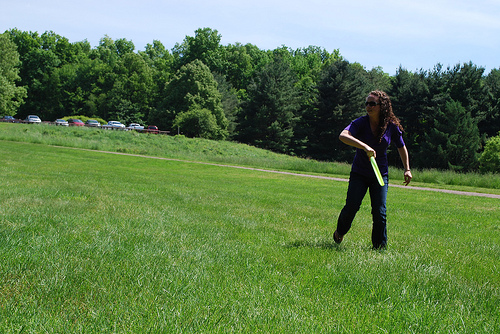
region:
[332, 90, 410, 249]
A woman wearing a t shirt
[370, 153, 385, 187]
A frisbee in someones hand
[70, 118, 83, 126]
A red sedan parked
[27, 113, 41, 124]
A car that is silver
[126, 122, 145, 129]
A truck that is parked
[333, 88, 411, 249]
A lady throwing a frisbee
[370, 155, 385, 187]
A green frisbee being thrown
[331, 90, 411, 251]
A woman wearing a purple t shirt throwing a frisbee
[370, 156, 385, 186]
A lime colored frisbee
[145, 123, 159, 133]
A parked bergundy car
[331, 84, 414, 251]
a woman holding a frisbee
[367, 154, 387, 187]
the frisbee is yellow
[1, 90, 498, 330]
the woman is standing in a field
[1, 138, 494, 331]
the field is green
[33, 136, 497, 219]
a small path going through the field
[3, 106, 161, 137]
cars are parked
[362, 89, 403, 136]
the woman has long hair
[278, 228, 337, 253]
a shadow in the grass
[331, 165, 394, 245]
the woman is wearing blue jeans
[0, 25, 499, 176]
the trees are tall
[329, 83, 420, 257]
woman wearing purple shirt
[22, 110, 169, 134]
cars out in the field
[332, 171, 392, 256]
blue jeans on the woman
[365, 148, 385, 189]
frisbee being held by woman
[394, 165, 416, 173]
watch on womans wrist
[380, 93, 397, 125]
curly brown hair on head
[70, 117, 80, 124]
red car in the field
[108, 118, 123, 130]
white car in the field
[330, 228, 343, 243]
sandals on the woman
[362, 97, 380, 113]
glasses on the face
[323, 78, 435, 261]
woman standing in the grass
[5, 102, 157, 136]
row of parked cars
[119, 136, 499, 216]
walking path cutting through the grass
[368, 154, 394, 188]
neon yellow frisbee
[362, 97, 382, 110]
sunglasses on the face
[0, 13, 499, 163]
thick, dark green trees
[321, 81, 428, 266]
woman holding a frisbee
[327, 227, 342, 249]
foot lifted off the ground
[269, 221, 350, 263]
shadow in the grass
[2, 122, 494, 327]
bright green grass on the ground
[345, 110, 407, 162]
the woma is wearing a short sleeve shirt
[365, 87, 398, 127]
the hair is brown in color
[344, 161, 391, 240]
the woman is wearing long pats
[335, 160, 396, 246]
the pants are blue in color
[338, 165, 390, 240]
the woman is wearing jeans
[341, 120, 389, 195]
the woman is holding a frisbee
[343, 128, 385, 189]
the woman is throwig a frisbee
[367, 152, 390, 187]
the frisbee is green in color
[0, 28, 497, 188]
a field of trees is in the background